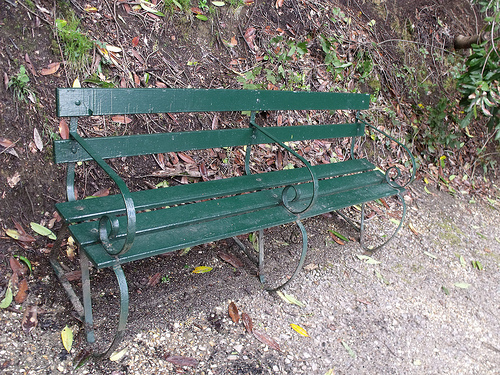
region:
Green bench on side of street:
[32, 66, 417, 353]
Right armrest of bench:
[355, 110, 425, 205]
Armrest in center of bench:
[246, 115, 321, 225]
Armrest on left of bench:
[65, 122, 145, 262]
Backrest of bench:
[39, 70, 381, 160]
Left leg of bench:
[63, 249, 143, 368]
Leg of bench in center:
[253, 217, 316, 306]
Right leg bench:
[356, 187, 408, 263]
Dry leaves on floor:
[213, 291, 288, 363]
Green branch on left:
[446, 21, 498, 145]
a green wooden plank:
[52, 85, 372, 117]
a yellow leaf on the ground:
[285, 320, 311, 340]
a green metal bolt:
[71, 95, 77, 101]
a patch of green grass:
[45, 10, 95, 62]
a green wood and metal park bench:
[45, 80, 420, 360]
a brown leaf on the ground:
[225, 297, 240, 324]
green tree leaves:
[285, 33, 310, 60]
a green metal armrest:
[65, 123, 143, 258]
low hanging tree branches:
[455, 0, 498, 130]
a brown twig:
[51, 38, 75, 87]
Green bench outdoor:
[30, 81, 425, 354]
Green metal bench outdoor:
[32, 77, 417, 348]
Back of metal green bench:
[40, 75, 400, 175]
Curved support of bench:
[51, 190, 412, 330]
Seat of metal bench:
[65, 155, 416, 280]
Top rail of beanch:
[50, 75, 375, 111]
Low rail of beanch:
[50, 115, 375, 155]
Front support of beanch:
[100, 190, 410, 331]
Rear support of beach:
[45, 225, 70, 280]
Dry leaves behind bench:
[22, 15, 460, 80]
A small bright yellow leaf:
[290, 316, 313, 339]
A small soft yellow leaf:
[55, 323, 77, 354]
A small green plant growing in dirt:
[15, 63, 30, 94]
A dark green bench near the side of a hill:
[50, 83, 399, 345]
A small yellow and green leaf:
[190, 264, 218, 274]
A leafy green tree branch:
[460, 26, 498, 126]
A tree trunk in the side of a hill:
[449, 28, 499, 44]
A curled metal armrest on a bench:
[266, 123, 322, 214]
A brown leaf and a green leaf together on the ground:
[328, 226, 350, 249]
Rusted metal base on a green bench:
[52, 226, 92, 316]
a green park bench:
[54, 83, 407, 363]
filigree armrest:
[66, 127, 138, 257]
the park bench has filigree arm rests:
[52, 84, 417, 361]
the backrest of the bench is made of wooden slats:
[56, 85, 373, 165]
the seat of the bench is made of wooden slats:
[54, 154, 402, 269]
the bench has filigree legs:
[46, 185, 408, 365]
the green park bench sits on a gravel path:
[51, 87, 436, 374]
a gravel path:
[0, 172, 497, 372]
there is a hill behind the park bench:
[2, 1, 495, 279]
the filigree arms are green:
[66, 122, 417, 257]